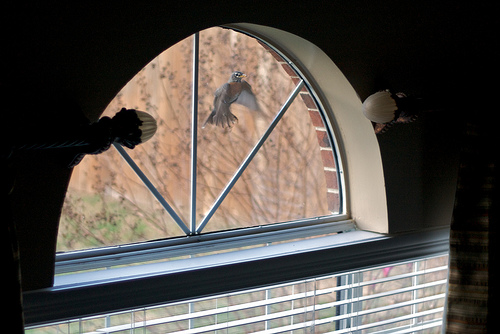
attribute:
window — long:
[21, 10, 458, 326]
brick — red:
[253, 40, 343, 216]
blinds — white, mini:
[22, 258, 487, 332]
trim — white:
[12, 211, 464, 328]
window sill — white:
[118, 222, 373, 295]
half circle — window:
[57, 22, 411, 261]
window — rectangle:
[27, 250, 448, 332]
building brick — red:
[299, 89, 320, 109]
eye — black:
[234, 73, 238, 76]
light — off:
[357, 80, 422, 136]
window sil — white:
[50, 228, 385, 290]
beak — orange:
[237, 72, 250, 86]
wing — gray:
[236, 99, 275, 112]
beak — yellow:
[241, 71, 248, 77]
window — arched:
[49, 22, 386, 292]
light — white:
[93, 109, 176, 161]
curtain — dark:
[382, 64, 495, 329]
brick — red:
[317, 167, 340, 193]